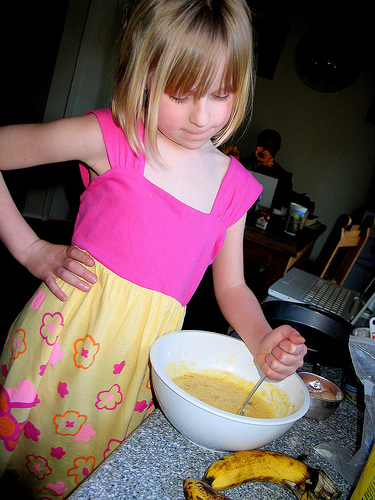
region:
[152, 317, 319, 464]
a girl making food.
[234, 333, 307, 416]
a metal mixing utensil.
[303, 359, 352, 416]
a bowl on a kitchen counter.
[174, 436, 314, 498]
a yellow banana on a counter.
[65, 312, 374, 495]
a kitchen counter top.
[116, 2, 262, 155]
a little girl with a hair cut.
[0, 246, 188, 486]
a yellow flower print dress.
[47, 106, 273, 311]
a pink top.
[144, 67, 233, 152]
a little girl's face.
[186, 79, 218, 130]
a little girl's nose.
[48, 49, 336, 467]
the girl is mixing a batter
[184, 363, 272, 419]
batter in the bowl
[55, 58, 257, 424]
girl is wearing a dress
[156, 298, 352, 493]
the bowl is on the counter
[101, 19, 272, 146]
the hair is blonde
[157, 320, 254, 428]
the batter is yellow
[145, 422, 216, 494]
the counter is gray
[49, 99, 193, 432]
the dress is pink and yellow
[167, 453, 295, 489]
the banana is yellow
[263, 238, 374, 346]
laptop on the counter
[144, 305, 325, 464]
she is stirring the mixture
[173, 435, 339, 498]
two over ripe bananas on the counter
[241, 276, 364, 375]
nonstick circular cake pan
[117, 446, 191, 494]
granite counter top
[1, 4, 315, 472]
girl in a pink and yellow dress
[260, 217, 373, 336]
open laptop computer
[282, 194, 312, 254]
plastic drinking cup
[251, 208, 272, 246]
pack of Marlboro cigarettes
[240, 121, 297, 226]
person sitting at a desk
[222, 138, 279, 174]
orange flowers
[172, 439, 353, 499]
The banana is yellow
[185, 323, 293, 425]
The girl is stirring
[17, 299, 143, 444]
The girl has flowers on her dress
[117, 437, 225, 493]
The counter is gray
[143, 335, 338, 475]
The bowl is white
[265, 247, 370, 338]
The laptop is gray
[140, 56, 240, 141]
The girl is looking down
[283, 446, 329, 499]
The banana has spots on it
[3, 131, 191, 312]
The girl has her hand on her hip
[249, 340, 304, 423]
The girl has a spoon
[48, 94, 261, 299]
girl's dress is pink and yellow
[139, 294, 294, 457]
she is mixing in bowl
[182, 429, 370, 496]
the bananas are yellow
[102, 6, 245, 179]
girl's hair is blonde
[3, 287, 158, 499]
flowers on girl's dress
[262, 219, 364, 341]
laptop is on counter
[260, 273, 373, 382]
black pan beside laptop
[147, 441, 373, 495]
banana has brown spots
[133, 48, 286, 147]
girl is looking at bowl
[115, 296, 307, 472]
the bowl is white